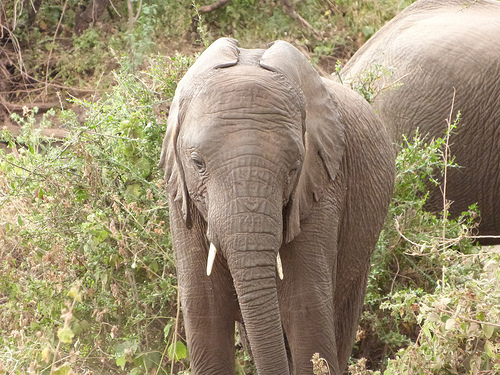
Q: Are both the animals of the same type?
A: Yes, all the animals are elephants.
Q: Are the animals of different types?
A: No, all the animals are elephants.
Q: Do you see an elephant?
A: Yes, there is an elephant.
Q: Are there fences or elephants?
A: Yes, there is an elephant.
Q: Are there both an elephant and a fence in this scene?
A: No, there is an elephant but no fences.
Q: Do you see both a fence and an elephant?
A: No, there is an elephant but no fences.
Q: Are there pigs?
A: No, there are no pigs.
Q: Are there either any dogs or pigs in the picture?
A: No, there are no pigs or dogs.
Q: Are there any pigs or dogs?
A: No, there are no pigs or dogs.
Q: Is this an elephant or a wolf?
A: This is an elephant.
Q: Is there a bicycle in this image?
A: No, there are no bicycles.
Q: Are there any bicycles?
A: No, there are no bicycles.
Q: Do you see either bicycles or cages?
A: No, there are no bicycles or cages.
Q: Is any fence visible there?
A: No, there are no fences.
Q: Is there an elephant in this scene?
A: Yes, there is an elephant.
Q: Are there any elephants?
A: Yes, there is an elephant.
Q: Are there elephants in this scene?
A: Yes, there is an elephant.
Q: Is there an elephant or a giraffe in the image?
A: Yes, there is an elephant.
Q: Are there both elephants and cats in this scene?
A: No, there is an elephant but no cats.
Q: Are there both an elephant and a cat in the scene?
A: No, there is an elephant but no cats.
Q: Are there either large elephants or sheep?
A: Yes, there is a large elephant.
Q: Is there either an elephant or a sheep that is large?
A: Yes, the elephant is large.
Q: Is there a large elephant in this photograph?
A: Yes, there is a large elephant.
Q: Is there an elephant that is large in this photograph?
A: Yes, there is a large elephant.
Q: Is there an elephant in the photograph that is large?
A: Yes, there is an elephant that is large.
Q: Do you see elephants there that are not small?
A: Yes, there is a large elephant.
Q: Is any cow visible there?
A: No, there are no cows.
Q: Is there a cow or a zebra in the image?
A: No, there are no cows or zebras.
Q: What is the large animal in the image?
A: The animal is an elephant.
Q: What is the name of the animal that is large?
A: The animal is an elephant.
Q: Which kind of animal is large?
A: The animal is an elephant.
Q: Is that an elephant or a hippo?
A: That is an elephant.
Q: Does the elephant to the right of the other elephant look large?
A: Yes, the elephant is large.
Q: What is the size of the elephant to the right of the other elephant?
A: The elephant is large.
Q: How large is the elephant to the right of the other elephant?
A: The elephant is large.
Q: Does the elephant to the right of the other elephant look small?
A: No, the elephant is large.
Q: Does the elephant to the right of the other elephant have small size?
A: No, the elephant is large.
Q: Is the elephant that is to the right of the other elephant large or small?
A: The elephant is large.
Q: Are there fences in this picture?
A: No, there are no fences.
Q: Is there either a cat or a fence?
A: No, there are no fences or cats.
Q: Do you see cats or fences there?
A: No, there are no fences or cats.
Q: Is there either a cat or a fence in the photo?
A: No, there are no fences or cats.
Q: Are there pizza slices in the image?
A: No, there are no pizza slices.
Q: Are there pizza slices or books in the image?
A: No, there are no pizza slices or books.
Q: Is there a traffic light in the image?
A: No, there are no traffic lights.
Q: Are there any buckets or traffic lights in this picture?
A: No, there are no traffic lights or buckets.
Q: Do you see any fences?
A: No, there are no fences.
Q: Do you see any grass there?
A: Yes, there is grass.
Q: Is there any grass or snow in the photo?
A: Yes, there is grass.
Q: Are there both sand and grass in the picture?
A: No, there is grass but no sand.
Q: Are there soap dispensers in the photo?
A: No, there are no soap dispensers.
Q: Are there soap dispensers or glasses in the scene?
A: No, there are no soap dispensers or glasses.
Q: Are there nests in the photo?
A: No, there are no nests.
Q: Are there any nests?
A: No, there are no nests.